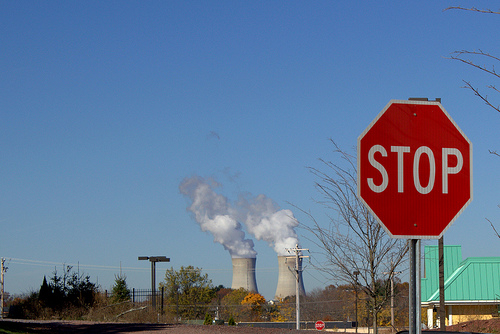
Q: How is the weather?
A: It is clear.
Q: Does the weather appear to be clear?
A: Yes, it is clear.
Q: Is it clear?
A: Yes, it is clear.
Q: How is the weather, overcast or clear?
A: It is clear.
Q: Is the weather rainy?
A: No, it is clear.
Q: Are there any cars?
A: No, there are no cars.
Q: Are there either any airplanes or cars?
A: No, there are no cars or airplanes.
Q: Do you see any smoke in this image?
A: Yes, there is smoke.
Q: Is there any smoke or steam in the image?
A: Yes, there is smoke.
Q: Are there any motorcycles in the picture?
A: No, there are no motorcycles.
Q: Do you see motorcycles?
A: No, there are no motorcycles.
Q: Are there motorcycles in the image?
A: No, there are no motorcycles.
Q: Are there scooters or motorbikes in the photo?
A: No, there are no motorbikes or scooters.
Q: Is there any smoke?
A: Yes, there is smoke.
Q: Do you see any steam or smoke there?
A: Yes, there is smoke.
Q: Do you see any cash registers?
A: No, there are no cash registers.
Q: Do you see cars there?
A: No, there are no cars.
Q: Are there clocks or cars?
A: No, there are no cars or clocks.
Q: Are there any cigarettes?
A: No, there are no cigarettes.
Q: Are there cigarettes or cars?
A: No, there are no cigarettes or cars.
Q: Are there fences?
A: Yes, there is a fence.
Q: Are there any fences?
A: Yes, there is a fence.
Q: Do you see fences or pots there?
A: Yes, there is a fence.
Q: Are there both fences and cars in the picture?
A: No, there is a fence but no cars.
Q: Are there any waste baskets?
A: No, there are no waste baskets.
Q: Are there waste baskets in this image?
A: No, there are no waste baskets.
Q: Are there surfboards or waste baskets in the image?
A: No, there are no waste baskets or surfboards.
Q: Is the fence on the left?
A: Yes, the fence is on the left of the image.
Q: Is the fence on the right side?
A: No, the fence is on the left of the image.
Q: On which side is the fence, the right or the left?
A: The fence is on the left of the image.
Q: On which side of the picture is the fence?
A: The fence is on the left of the image.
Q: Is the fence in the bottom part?
A: Yes, the fence is in the bottom of the image.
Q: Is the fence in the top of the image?
A: No, the fence is in the bottom of the image.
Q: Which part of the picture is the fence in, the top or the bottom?
A: The fence is in the bottom of the image.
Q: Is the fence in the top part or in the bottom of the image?
A: The fence is in the bottom of the image.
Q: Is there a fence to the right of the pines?
A: Yes, there is a fence to the right of the pines.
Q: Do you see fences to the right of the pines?
A: Yes, there is a fence to the right of the pines.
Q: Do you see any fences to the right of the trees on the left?
A: Yes, there is a fence to the right of the pines.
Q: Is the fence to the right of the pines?
A: Yes, the fence is to the right of the pines.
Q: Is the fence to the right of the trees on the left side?
A: Yes, the fence is to the right of the pines.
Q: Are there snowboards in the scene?
A: No, there are no snowboards.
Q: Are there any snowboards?
A: No, there are no snowboards.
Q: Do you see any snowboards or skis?
A: No, there are no snowboards or skis.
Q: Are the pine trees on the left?
A: Yes, the pine trees are on the left of the image.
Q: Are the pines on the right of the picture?
A: No, the pines are on the left of the image.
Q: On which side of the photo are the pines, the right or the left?
A: The pines are on the left of the image.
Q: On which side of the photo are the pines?
A: The pines are on the left of the image.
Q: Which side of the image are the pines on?
A: The pines are on the left of the image.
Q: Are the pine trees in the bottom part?
A: Yes, the pine trees are in the bottom of the image.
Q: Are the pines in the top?
A: No, the pines are in the bottom of the image.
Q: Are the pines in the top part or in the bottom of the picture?
A: The pines are in the bottom of the image.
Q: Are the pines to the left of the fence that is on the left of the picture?
A: Yes, the pines are to the left of the fence.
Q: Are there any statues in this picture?
A: No, there are no statues.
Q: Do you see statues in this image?
A: No, there are no statues.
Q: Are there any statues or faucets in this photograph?
A: No, there are no statues or faucets.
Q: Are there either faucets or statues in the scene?
A: No, there are no statues or faucets.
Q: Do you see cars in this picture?
A: No, there are no cars.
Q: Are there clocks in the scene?
A: No, there are no clocks.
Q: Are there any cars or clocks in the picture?
A: No, there are no clocks or cars.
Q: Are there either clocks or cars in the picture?
A: No, there are no cars or clocks.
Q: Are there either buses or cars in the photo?
A: No, there are no cars or buses.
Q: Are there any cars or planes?
A: No, there are no cars or planes.